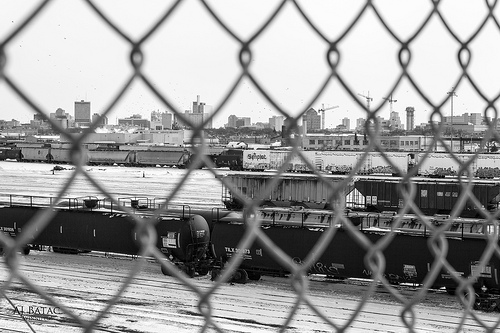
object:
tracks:
[3, 231, 494, 294]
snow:
[84, 286, 115, 315]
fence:
[6, 5, 496, 331]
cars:
[17, 161, 497, 301]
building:
[21, 106, 496, 179]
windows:
[306, 138, 317, 145]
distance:
[3, 124, 493, 138]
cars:
[7, 126, 257, 185]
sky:
[4, 3, 498, 123]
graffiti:
[254, 166, 495, 178]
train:
[219, 172, 499, 212]